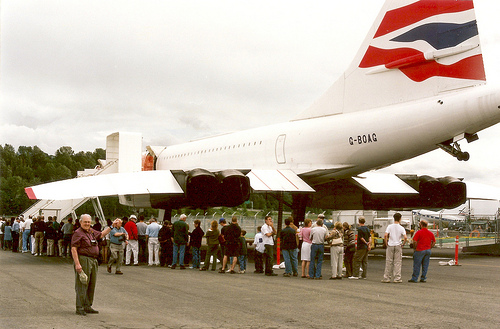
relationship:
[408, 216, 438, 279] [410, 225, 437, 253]
man wearing a shirt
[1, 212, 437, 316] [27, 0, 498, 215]
people outside of airplane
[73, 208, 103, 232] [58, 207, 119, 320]
face of an man